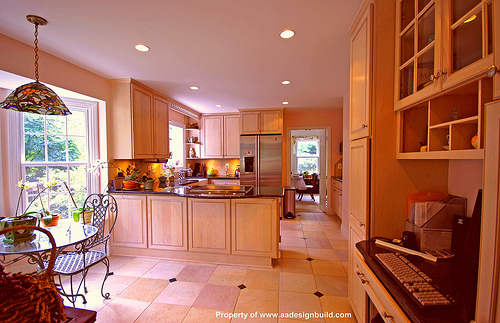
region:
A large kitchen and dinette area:
[6, 10, 491, 312]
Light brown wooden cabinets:
[141, 199, 293, 254]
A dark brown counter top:
[111, 177, 288, 207]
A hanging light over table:
[10, 35, 82, 135]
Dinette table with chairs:
[6, 199, 95, 270]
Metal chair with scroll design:
[76, 183, 114, 298]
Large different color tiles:
[132, 255, 269, 322]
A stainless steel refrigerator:
[238, 137, 288, 191]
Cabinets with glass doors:
[388, 17, 490, 106]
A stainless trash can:
[283, 184, 296, 226]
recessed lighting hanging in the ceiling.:
[274, 2, 298, 115]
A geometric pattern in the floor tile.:
[290, 220, 342, 318]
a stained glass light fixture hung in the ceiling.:
[2, 84, 74, 117]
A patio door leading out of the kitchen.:
[22, 97, 110, 277]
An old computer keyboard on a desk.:
[370, 247, 461, 309]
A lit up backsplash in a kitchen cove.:
[112, 155, 289, 195]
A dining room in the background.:
[296, 167, 325, 200]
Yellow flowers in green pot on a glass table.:
[4, 173, 62, 246]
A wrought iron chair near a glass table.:
[37, 191, 119, 303]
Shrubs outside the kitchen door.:
[32, 119, 100, 214]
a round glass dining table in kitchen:
[0, 216, 97, 304]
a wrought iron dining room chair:
[39, 192, 117, 301]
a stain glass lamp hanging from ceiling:
[1, 14, 71, 116]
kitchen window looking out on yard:
[0, 88, 100, 220]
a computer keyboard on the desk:
[370, 249, 457, 311]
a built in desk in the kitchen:
[352, 238, 475, 322]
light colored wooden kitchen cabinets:
[106, 191, 279, 269]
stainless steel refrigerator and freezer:
[237, 133, 283, 196]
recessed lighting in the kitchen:
[134, 44, 150, 53]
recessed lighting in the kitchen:
[279, 30, 293, 38]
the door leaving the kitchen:
[287, 127, 330, 210]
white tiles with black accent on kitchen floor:
[2, 211, 359, 321]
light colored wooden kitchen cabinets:
[106, 78, 285, 159]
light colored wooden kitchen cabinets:
[347, 21, 497, 321]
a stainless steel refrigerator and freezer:
[237, 133, 283, 199]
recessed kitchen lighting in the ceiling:
[134, 43, 149, 54]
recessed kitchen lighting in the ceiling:
[280, 28, 294, 39]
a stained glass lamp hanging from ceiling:
[0, 14, 74, 118]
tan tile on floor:
[307, 235, 327, 249]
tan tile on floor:
[284, 242, 307, 257]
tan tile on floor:
[282, 254, 312, 271]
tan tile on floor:
[313, 259, 348, 273]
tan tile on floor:
[316, 273, 348, 295]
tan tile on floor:
[283, 269, 310, 289]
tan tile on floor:
[248, 269, 279, 288]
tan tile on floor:
[217, 264, 241, 284]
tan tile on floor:
[176, 258, 211, 280]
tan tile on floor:
[141, 258, 177, 279]